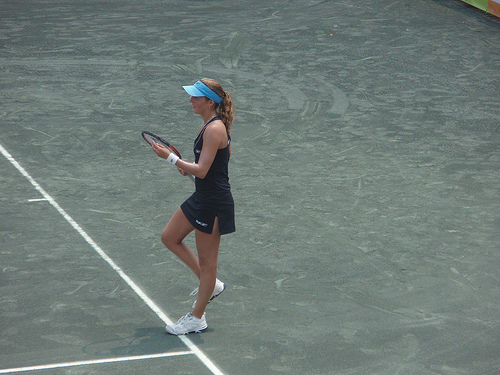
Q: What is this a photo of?
A: A tennis player.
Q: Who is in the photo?
A: A young girl.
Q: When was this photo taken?
A: During a tennis match.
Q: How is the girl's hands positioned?
A: They are holding a tennis racket.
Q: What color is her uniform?
A: Black.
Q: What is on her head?
A: A sun-visor.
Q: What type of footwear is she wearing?
A: Sneakers.